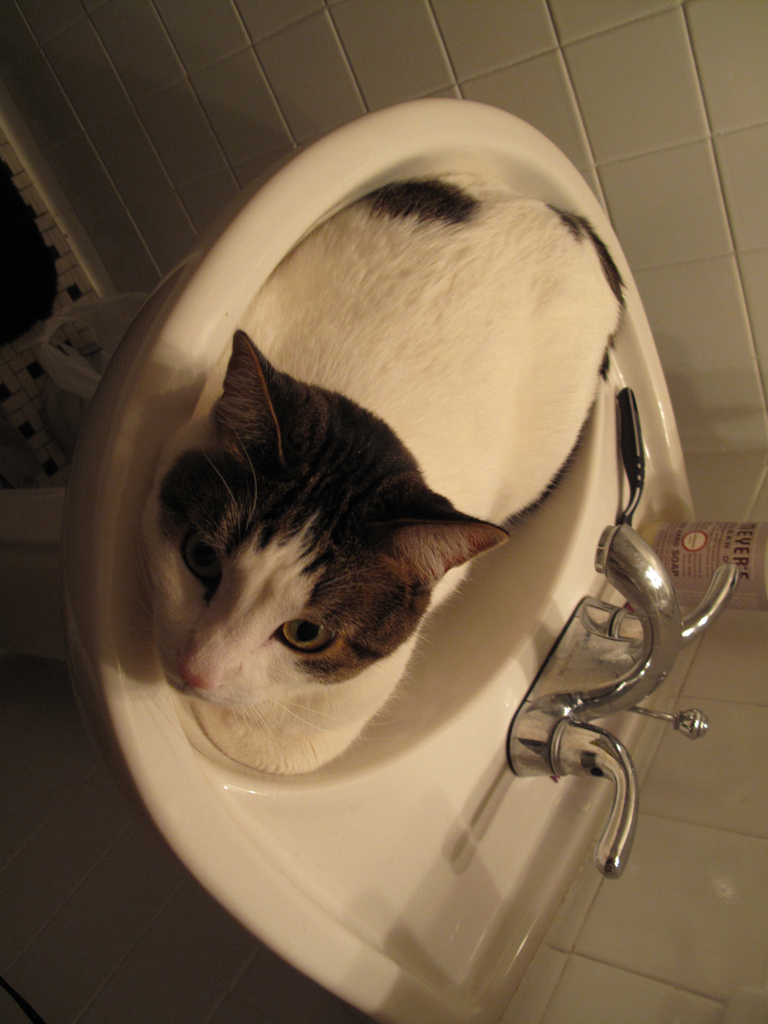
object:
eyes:
[282, 618, 337, 653]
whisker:
[244, 681, 382, 745]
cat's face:
[144, 432, 387, 750]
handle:
[565, 721, 641, 877]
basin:
[63, 88, 697, 1020]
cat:
[133, 173, 627, 770]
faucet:
[508, 520, 743, 877]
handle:
[608, 381, 652, 523]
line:
[620, 380, 651, 471]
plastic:
[32, 297, 101, 451]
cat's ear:
[375, 506, 511, 589]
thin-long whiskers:
[261, 714, 324, 757]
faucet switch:
[553, 709, 637, 876]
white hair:
[336, 173, 516, 388]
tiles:
[77, 79, 248, 208]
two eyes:
[179, 527, 339, 656]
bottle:
[638, 518, 767, 612]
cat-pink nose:
[177, 654, 211, 692]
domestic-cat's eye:
[180, 525, 223, 596]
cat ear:
[232, 330, 289, 471]